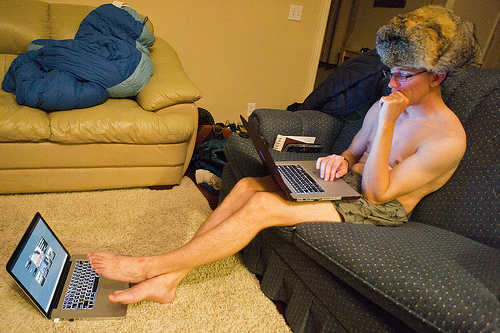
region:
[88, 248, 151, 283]
foot of computer perdon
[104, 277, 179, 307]
Foot of computer person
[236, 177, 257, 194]
Knee of computer person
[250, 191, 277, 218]
knee of computer person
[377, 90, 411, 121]
Hand of computer person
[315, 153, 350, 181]
Hand of computer person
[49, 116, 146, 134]
Part of comfortable beige couch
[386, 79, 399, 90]
Nose of computer person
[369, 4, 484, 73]
Furry hat of working person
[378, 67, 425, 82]
Glasses of workingg person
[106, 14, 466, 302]
Shirtless man sitting and using a laptop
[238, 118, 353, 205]
Laptop the man is using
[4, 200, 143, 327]
Another laptop at the man's feet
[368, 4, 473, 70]
Fur hat the man is wearing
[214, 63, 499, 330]
Grey spotted chouch the man is sitting on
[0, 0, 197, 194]
A second cream couch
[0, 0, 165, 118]
A comforter or sleeping bag on the second couch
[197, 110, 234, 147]
A backpack beside the two couches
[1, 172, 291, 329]
A white rug on the floor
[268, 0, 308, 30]
Two light switches on the wall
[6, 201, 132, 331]
silver laptop on floor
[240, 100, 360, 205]
laptop on the man's lap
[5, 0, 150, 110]
blue blanket on the couch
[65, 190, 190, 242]
beige carpet on the floor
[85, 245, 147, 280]
the man's left foot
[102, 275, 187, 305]
the man's right foot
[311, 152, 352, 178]
the man's right hand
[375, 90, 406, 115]
the man's left hand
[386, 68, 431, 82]
glasses on the man's face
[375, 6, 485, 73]
hat on man's head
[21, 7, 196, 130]
a blue sleeping bag on a couch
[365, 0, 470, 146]
a man wearing a fur hat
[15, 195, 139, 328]
a laptop next to a man's feet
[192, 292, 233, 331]
a fluffy white carpet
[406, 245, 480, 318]
a blue polka dot couch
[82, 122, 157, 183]
a cream colored leather couch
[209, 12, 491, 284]
a shirtless man working on a laptop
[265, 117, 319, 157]
papers stuffed in a couch cushion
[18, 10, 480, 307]
an untidy living room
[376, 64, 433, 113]
a man wearing glasses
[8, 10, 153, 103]
a blue sleeping bag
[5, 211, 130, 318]
a laptop on the floor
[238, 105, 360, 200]
a laptop on the mans lap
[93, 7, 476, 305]
a man sitting on the couch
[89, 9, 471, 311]
a man looking at a laptop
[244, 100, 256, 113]
an electrical outlet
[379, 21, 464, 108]
a man wearing a hat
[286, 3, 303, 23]
a light switch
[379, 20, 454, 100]
a man wearing glasses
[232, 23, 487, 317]
a blue couch